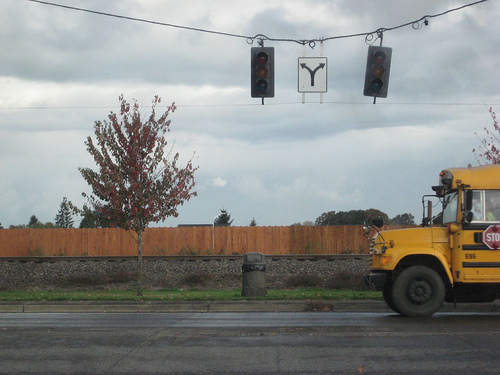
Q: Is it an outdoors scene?
A: Yes, it is outdoors.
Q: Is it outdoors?
A: Yes, it is outdoors.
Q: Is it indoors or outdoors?
A: It is outdoors.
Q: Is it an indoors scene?
A: No, it is outdoors.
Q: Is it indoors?
A: No, it is outdoors.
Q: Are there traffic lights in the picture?
A: Yes, there is a traffic light.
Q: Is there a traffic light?
A: Yes, there is a traffic light.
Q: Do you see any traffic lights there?
A: Yes, there is a traffic light.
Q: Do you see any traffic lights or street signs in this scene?
A: Yes, there is a traffic light.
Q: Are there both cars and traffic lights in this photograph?
A: No, there is a traffic light but no cars.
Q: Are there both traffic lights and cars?
A: No, there is a traffic light but no cars.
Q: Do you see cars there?
A: No, there are no cars.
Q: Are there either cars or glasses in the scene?
A: No, there are no cars or glasses.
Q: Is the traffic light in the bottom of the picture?
A: No, the traffic light is in the top of the image.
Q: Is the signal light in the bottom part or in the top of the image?
A: The signal light is in the top of the image.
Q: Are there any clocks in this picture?
A: No, there are no clocks.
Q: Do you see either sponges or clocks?
A: No, there are no clocks or sponges.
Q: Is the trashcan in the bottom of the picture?
A: Yes, the trashcan is in the bottom of the image.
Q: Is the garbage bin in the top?
A: No, the garbage bin is in the bottom of the image.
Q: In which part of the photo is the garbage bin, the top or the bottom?
A: The garbage bin is in the bottom of the image.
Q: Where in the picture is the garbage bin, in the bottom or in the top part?
A: The garbage bin is in the bottom of the image.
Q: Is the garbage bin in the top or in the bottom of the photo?
A: The garbage bin is in the bottom of the image.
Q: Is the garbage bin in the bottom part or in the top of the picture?
A: The garbage bin is in the bottom of the image.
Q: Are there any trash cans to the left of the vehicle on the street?
A: Yes, there is a trash can to the left of the bus.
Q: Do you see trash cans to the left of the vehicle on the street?
A: Yes, there is a trash can to the left of the bus.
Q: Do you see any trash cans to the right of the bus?
A: No, the trash can is to the left of the bus.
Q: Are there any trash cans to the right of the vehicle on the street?
A: No, the trash can is to the left of the bus.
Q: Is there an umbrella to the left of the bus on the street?
A: No, there is a trash can to the left of the bus.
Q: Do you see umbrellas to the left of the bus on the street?
A: No, there is a trash can to the left of the bus.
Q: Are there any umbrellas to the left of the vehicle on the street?
A: No, there is a trash can to the left of the bus.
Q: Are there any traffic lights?
A: Yes, there is a traffic light.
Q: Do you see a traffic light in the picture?
A: Yes, there is a traffic light.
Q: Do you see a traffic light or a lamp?
A: Yes, there is a traffic light.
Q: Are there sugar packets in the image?
A: No, there are no sugar packets.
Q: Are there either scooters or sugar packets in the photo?
A: No, there are no sugar packets or scooters.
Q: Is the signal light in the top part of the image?
A: Yes, the signal light is in the top of the image.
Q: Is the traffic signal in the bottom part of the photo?
A: No, the traffic signal is in the top of the image.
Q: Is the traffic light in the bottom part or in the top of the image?
A: The traffic light is in the top of the image.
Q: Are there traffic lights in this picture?
A: Yes, there is a traffic light.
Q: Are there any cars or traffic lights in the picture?
A: Yes, there is a traffic light.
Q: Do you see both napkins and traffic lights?
A: No, there is a traffic light but no napkins.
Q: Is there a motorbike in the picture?
A: No, there are no motorcycles.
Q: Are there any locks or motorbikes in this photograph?
A: No, there are no motorbikes or locks.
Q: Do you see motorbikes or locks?
A: No, there are no motorbikes or locks.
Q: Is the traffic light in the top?
A: Yes, the traffic light is in the top of the image.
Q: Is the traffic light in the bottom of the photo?
A: No, the traffic light is in the top of the image.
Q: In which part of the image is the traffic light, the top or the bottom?
A: The traffic light is in the top of the image.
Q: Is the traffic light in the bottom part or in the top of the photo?
A: The traffic light is in the top of the image.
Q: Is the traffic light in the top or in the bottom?
A: The traffic light is in the top of the image.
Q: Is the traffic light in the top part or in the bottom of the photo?
A: The traffic light is in the top of the image.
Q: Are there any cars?
A: No, there are no cars.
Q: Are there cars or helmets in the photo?
A: No, there are no cars or helmets.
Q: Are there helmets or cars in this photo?
A: No, there are no cars or helmets.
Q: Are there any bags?
A: No, there are no bags.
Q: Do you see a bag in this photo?
A: No, there are no bags.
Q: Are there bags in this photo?
A: No, there are no bags.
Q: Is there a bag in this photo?
A: No, there are no bags.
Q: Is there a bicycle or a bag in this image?
A: No, there are no bags or bicycles.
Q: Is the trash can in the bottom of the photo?
A: Yes, the trash can is in the bottom of the image.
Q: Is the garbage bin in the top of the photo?
A: No, the garbage bin is in the bottom of the image.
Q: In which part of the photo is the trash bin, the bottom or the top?
A: The trash bin is in the bottom of the image.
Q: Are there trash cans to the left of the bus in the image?
A: Yes, there is a trash can to the left of the bus.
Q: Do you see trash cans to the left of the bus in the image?
A: Yes, there is a trash can to the left of the bus.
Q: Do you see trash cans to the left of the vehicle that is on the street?
A: Yes, there is a trash can to the left of the bus.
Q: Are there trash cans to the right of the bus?
A: No, the trash can is to the left of the bus.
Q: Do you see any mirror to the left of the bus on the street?
A: No, there is a trash can to the left of the bus.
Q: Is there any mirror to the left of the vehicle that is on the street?
A: No, there is a trash can to the left of the bus.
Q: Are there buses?
A: Yes, there is a bus.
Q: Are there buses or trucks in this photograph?
A: Yes, there is a bus.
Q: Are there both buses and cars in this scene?
A: No, there is a bus but no cars.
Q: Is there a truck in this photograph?
A: No, there are no trucks.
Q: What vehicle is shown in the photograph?
A: The vehicle is a bus.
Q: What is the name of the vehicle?
A: The vehicle is a bus.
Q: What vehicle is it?
A: The vehicle is a bus.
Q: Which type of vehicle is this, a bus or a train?
A: That is a bus.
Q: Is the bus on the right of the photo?
A: Yes, the bus is on the right of the image.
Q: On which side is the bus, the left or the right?
A: The bus is on the right of the image.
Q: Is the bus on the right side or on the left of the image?
A: The bus is on the right of the image.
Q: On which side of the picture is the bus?
A: The bus is on the right of the image.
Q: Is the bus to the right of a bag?
A: No, the bus is to the right of a trash can.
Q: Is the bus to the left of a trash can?
A: No, the bus is to the right of a trash can.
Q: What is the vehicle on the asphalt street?
A: The vehicle is a bus.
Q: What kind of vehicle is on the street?
A: The vehicle is a bus.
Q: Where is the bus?
A: The bus is on the street.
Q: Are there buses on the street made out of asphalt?
A: Yes, there is a bus on the street.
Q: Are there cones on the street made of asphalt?
A: No, there is a bus on the street.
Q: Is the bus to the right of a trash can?
A: Yes, the bus is to the right of a trash can.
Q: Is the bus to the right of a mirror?
A: No, the bus is to the right of a trash can.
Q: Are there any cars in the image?
A: No, there are no cars.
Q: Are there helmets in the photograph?
A: No, there are no helmets.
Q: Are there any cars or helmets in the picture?
A: No, there are no helmets or cars.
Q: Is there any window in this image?
A: Yes, there is a window.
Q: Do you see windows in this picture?
A: Yes, there is a window.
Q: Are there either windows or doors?
A: Yes, there is a window.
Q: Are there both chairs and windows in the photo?
A: No, there is a window but no chairs.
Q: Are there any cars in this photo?
A: No, there are no cars.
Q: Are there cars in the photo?
A: No, there are no cars.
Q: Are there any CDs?
A: No, there are no cds.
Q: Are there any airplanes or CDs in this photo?
A: No, there are no CDs or airplanes.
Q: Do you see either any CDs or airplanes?
A: No, there are no CDs or airplanes.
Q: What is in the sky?
A: The clouds are in the sky.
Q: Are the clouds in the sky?
A: Yes, the clouds are in the sky.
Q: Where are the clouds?
A: The clouds are in the sky.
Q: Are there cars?
A: No, there are no cars.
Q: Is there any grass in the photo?
A: Yes, there is grass.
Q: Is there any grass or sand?
A: Yes, there is grass.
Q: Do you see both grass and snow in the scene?
A: No, there is grass but no snow.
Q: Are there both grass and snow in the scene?
A: No, there is grass but no snow.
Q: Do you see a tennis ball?
A: No, there are no tennis balls.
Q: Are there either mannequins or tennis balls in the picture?
A: No, there are no tennis balls or mannequins.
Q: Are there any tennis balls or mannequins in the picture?
A: No, there are no tennis balls or mannequins.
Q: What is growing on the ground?
A: The grass is growing on the ground.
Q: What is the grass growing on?
A: The grass is growing on the ground.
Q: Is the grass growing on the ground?
A: Yes, the grass is growing on the ground.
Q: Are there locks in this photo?
A: No, there are no locks.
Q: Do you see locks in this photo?
A: No, there are no locks.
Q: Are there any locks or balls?
A: No, there are no locks or balls.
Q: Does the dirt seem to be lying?
A: Yes, the dirt is lying.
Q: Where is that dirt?
A: The dirt is on the street.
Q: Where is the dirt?
A: The dirt is on the street.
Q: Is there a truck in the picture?
A: No, there are no trucks.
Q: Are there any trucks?
A: No, there are no trucks.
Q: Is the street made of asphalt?
A: Yes, the street is made of asphalt.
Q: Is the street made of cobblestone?
A: No, the street is made of asphalt.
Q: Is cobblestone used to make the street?
A: No, the street is made of asphalt.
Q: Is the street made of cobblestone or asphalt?
A: The street is made of asphalt.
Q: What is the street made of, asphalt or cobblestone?
A: The street is made of asphalt.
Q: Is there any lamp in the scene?
A: No, there are no lamps.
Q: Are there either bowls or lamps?
A: No, there are no lamps or bowls.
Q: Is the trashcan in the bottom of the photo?
A: Yes, the trashcan is in the bottom of the image.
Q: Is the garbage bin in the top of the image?
A: No, the garbage bin is in the bottom of the image.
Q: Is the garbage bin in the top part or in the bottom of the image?
A: The garbage bin is in the bottom of the image.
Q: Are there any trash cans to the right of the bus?
A: No, the trash can is to the left of the bus.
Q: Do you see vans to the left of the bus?
A: No, there is a trash can to the left of the bus.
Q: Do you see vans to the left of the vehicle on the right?
A: No, there is a trash can to the left of the bus.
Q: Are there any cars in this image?
A: No, there are no cars.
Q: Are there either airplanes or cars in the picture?
A: No, there are no cars or airplanes.